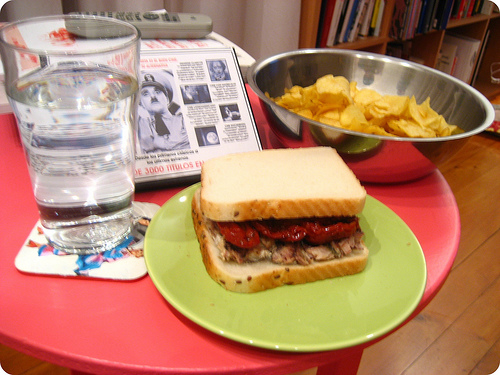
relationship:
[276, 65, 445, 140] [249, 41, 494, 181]
chips in bowl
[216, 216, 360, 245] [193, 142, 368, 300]
peppers on sandwich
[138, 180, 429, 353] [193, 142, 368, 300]
plate with sandwich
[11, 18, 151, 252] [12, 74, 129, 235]
glass of water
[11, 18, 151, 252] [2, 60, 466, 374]
glass on table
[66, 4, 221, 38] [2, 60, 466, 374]
remote on table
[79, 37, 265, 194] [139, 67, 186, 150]
dvd case with picture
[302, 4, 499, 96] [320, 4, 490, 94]
bookcase with books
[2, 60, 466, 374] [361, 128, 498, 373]
table on floor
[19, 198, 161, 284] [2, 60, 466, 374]
coaster on table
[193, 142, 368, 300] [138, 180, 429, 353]
sandwich on a plate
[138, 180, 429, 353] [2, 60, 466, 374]
plate on table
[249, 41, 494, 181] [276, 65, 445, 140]
bowl of chips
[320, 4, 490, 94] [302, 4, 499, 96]
books on bookcase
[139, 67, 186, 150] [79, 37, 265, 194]
picture on dvd case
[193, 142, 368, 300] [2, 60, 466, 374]
sandwich on table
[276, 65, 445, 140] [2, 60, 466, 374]
chips on table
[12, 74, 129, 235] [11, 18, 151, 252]
water in glass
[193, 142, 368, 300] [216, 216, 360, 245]
sandwich with peppers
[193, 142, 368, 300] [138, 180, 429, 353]
sandwich on plate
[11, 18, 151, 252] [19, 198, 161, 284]
glass on a coaster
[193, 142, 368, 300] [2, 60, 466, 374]
sandwich sitting on table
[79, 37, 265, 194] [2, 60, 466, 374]
dvd case on table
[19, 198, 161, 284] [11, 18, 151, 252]
coaster under glass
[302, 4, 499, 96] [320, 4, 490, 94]
bookcase filled with books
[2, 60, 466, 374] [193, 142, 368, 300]
table with sandwich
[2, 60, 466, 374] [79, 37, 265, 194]
table with dvd case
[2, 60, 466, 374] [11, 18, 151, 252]
table with glass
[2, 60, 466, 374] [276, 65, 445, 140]
table with chips